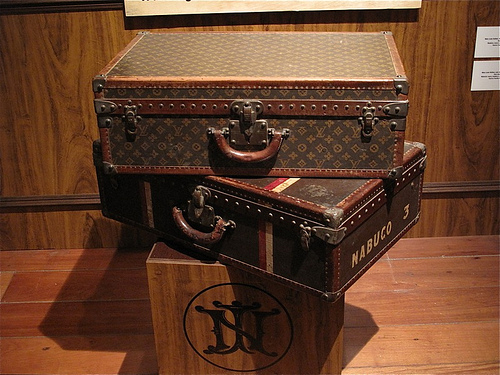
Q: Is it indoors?
A: Yes, it is indoors.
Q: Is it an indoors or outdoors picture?
A: It is indoors.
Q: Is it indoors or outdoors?
A: It is indoors.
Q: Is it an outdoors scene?
A: No, it is indoors.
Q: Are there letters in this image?
A: Yes, there are letters.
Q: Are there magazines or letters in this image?
A: Yes, there are letters.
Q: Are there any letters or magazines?
A: Yes, there are letters.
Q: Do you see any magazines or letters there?
A: Yes, there are letters.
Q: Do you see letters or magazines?
A: Yes, there are letters.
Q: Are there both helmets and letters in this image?
A: No, there are letters but no helmets.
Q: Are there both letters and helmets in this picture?
A: No, there are letters but no helmets.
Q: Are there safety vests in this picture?
A: No, there are no safety vests.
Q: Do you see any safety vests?
A: No, there are no safety vests.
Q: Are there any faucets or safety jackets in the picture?
A: No, there are no safety jackets or faucets.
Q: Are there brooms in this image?
A: No, there are no brooms.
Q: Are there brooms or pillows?
A: No, there are no brooms or pillows.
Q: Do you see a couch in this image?
A: No, there are no couches.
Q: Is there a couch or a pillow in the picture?
A: No, there are no couches or pillows.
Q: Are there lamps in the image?
A: No, there are no lamps.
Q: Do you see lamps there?
A: No, there are no lamps.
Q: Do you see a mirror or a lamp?
A: No, there are no lamps or mirrors.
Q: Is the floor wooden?
A: Yes, the floor is wooden.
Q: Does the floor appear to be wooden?
A: Yes, the floor is wooden.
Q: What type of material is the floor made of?
A: The floor is made of wood.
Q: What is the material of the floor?
A: The floor is made of wood.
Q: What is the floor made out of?
A: The floor is made of wood.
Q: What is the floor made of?
A: The floor is made of wood.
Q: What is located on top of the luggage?
A: The box is on top of the luggage.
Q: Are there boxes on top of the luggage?
A: Yes, there is a box on top of the luggage.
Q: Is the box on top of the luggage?
A: Yes, the box is on top of the luggage.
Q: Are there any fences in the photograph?
A: No, there are no fences.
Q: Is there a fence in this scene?
A: No, there are no fences.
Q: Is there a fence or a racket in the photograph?
A: No, there are no fences or rackets.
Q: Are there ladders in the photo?
A: No, there are no ladders.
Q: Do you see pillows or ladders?
A: No, there are no ladders or pillows.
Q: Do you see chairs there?
A: No, there are no chairs.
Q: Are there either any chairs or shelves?
A: No, there are no chairs or shelves.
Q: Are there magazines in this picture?
A: No, there are no magazines.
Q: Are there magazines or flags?
A: No, there are no magazines or flags.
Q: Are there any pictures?
A: No, there are no pictures.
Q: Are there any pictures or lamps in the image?
A: No, there are no pictures or lamps.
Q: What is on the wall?
A: The cards are on the wall.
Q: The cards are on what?
A: The cards are on the wall.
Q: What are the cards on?
A: The cards are on the wall.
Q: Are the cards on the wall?
A: Yes, the cards are on the wall.